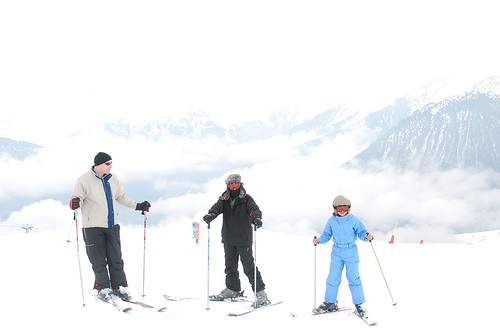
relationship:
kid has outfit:
[313, 195, 372, 319] [320, 212, 365, 304]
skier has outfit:
[205, 173, 271, 307] [210, 189, 266, 291]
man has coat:
[70, 151, 149, 303] [73, 170, 137, 228]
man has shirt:
[70, 151, 149, 303] [100, 173, 115, 226]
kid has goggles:
[313, 195, 372, 319] [334, 204, 350, 213]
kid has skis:
[313, 195, 372, 319] [291, 302, 375, 326]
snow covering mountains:
[89, 74, 466, 125] [0, 69, 500, 194]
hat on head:
[93, 152, 111, 165] [93, 153, 111, 176]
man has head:
[70, 151, 149, 303] [93, 153, 111, 176]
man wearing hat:
[70, 151, 149, 303] [93, 152, 111, 165]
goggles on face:
[227, 182, 242, 189] [227, 181, 241, 196]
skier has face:
[205, 173, 271, 307] [227, 181, 241, 196]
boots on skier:
[214, 288, 271, 306] [205, 173, 271, 307]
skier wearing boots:
[205, 173, 271, 307] [214, 288, 271, 306]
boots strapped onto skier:
[214, 288, 271, 306] [205, 173, 271, 307]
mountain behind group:
[344, 75, 499, 177] [69, 152, 397, 327]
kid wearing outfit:
[313, 195, 372, 319] [320, 212, 365, 304]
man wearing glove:
[70, 151, 149, 303] [69, 197, 80, 209]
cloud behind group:
[207, 156, 495, 230] [69, 152, 397, 327]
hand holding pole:
[68, 195, 83, 212] [71, 207, 87, 307]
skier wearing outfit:
[205, 173, 271, 307] [210, 189, 266, 291]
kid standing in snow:
[313, 195, 372, 319] [10, 231, 499, 333]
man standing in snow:
[70, 151, 149, 303] [10, 231, 499, 333]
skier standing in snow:
[205, 173, 271, 307] [10, 231, 499, 333]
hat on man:
[93, 152, 111, 165] [70, 151, 149, 303]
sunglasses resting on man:
[102, 160, 111, 167] [70, 151, 149, 303]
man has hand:
[70, 151, 149, 303] [68, 195, 83, 212]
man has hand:
[70, 151, 149, 303] [135, 200, 153, 211]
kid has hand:
[313, 195, 372, 319] [311, 236, 321, 247]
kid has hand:
[313, 195, 372, 319] [364, 233, 374, 242]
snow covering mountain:
[89, 74, 466, 125] [344, 75, 499, 177]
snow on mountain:
[411, 72, 498, 112] [344, 75, 499, 177]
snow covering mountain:
[411, 72, 498, 112] [344, 75, 499, 177]